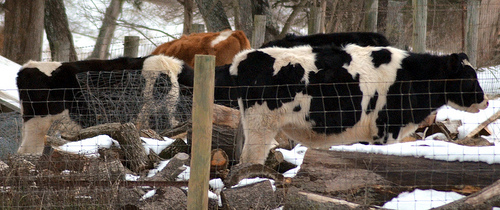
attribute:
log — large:
[319, 139, 499, 188]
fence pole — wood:
[194, 54, 207, 209]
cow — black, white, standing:
[231, 45, 491, 176]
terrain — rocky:
[315, 150, 374, 205]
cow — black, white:
[225, 25, 485, 177]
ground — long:
[23, 124, 183, 208]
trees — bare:
[103, 16, 155, 47]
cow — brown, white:
[232, 50, 484, 165]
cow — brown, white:
[16, 59, 201, 152]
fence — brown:
[7, 67, 497, 204]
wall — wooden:
[470, 32, 479, 52]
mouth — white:
[471, 93, 492, 113]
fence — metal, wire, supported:
[21, 16, 466, 208]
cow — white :
[251, 33, 483, 185]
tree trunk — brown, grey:
[5, 2, 45, 62]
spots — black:
[289, 50, 390, 121]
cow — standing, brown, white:
[160, 31, 249, 60]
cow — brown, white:
[151, 29, 256, 90]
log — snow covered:
[299, 145, 492, 205]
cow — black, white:
[235, 39, 477, 152]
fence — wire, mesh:
[0, 55, 497, 209]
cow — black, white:
[209, 23, 496, 165]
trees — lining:
[3, 5, 498, 51]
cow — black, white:
[249, 52, 413, 122]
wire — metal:
[5, 71, 498, 208]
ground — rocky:
[4, 97, 498, 208]